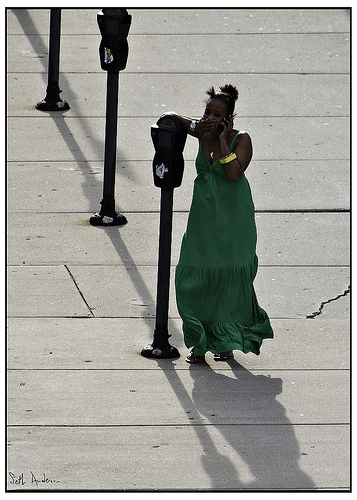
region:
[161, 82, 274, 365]
brown haired woman leaning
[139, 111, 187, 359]
tall black parking meter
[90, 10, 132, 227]
tall black parking meter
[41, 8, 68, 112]
tall black parking meter pole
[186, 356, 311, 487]
shadow of woman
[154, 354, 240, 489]
shadow of parking meter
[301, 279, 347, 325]
wide long crack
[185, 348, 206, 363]
black open toed flip flop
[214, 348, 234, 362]
black open toed flip flop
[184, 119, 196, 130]
silver banded wrist watch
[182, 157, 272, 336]
Long green ruffled dress.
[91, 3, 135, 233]
Parking Meter in plaza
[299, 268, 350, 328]
Plaza tile has crack.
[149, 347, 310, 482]
Shadow of woman and parking meter.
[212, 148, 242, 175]
Yellow bracelet on wrist.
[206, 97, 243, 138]
Talking with cell phone.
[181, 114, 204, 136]
Wristwatch on right arm.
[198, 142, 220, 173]
Silver necklace on neck.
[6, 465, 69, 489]
Seth Anderson signature left.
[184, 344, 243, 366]
Her favorite flip~flops.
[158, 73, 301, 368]
woman wearing long green dress with ruffled hem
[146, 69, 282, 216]
woman with right arm leaning on parking meter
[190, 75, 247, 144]
woman covering her mouth with the palm of one hand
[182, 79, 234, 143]
woman holding cellphone to ear while showing emotion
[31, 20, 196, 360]
row of black parking meters with white labels stuck on them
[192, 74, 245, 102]
smooth hair with bunches of hair sticking up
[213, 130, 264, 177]
chunky yellow bracelet next to beaded bracelet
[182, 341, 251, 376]
toes in sandals peeking out from bottom of hem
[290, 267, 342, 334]
jagged crack in surface of ground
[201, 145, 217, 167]
shiny silver pendant hanging above dress neckline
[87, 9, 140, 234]
black parking meter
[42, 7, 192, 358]
row of black parking meters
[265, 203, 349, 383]
cracked cement side walks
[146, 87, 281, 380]
black woman taking a break to talk on the cell phone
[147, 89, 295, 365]
black woman in green dress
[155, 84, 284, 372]
black woman astonished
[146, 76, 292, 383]
black woman suprised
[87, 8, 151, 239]
black city parking meter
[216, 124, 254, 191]
gold colored bracelet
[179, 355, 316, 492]
shadow of a woman and parking meter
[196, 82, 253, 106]
a bun type hairstyle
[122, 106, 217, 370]
parking meter on walkway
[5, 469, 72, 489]
Seth Anderson written in corner of photo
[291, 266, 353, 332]
crack in concrete boarwalk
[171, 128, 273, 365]
emerald green sundress blowing in wind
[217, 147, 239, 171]
square boxy yellow bracelet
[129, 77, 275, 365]
woman leaning against meter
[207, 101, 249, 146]
cell phone in woman's hand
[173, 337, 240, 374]
sandals on woman's feet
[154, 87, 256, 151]
woman with her hand across her mouth